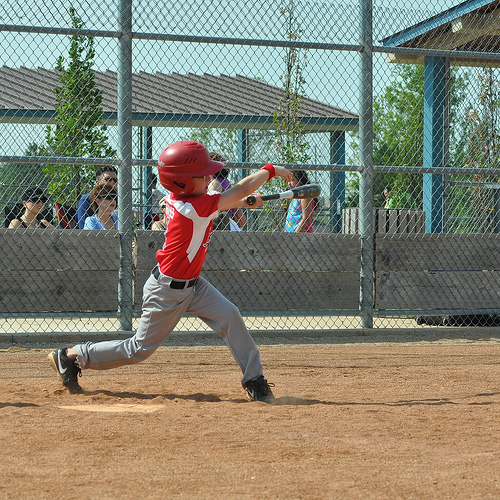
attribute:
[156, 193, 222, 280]
shirt — red, white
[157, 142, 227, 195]
helmet — red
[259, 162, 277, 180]
bracelet — red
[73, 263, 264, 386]
pants — grey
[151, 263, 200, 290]
belt — black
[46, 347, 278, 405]
shoes — black, white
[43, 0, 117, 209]
tree — green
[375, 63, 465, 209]
tree — green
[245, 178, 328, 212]
baseball — little league, wooden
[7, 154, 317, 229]
people — in back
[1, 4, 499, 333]
fence — chain link, in back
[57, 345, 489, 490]
baseball diamond — partially shown, dirt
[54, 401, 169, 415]
home plate — dirty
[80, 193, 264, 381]
uniform — red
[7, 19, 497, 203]
trees — in back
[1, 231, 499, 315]
wooden boards — on fence